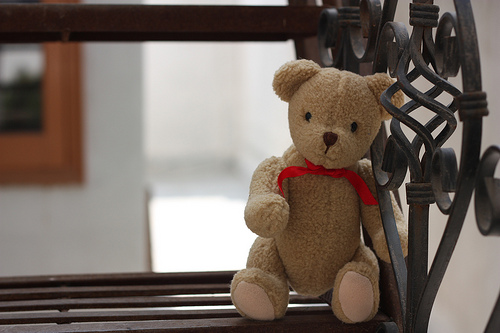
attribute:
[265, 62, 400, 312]
teddy — stuffed, brown, black, tan, sitting, alone, sunny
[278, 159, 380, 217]
ribbon — red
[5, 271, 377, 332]
bench — iron, black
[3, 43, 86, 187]
picture — blurry, wooden, hanging